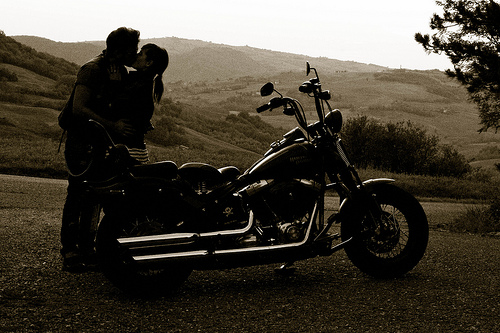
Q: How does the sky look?
A: Grey and overcast.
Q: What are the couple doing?
A: Kissing.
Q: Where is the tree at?
A: Upper right hand corner.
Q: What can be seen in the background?
A: Mountains.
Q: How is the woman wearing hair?
A: In a ponytail.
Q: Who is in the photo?
A: Two people.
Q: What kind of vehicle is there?
A: Motorcycle.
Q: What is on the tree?
A: Leaves.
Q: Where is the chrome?
A: On motorcycle.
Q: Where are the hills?
A: Behind people.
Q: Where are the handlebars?
A: On motorcycle.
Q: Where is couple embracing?
A: By motorcycle.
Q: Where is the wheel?
A: On motorcycle.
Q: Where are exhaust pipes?
A: Motorcycle.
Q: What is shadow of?
A: Mountains.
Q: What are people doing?
A: Embracing.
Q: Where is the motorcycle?
A: On the road.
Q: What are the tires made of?
A: Rubber.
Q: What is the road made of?
A: Asphalt.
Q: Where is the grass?
A: Next to the road.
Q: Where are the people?
A: Behind the motorcycle.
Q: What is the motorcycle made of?
A: Metal.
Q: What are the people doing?
A: Kissing.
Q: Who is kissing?
A: The man and the woman.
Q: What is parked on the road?
A: The motorcycle.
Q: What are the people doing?
A: Kissing.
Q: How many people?
A: Two.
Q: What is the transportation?
A: A motorcycle.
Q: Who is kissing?
A: People.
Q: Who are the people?
A: A couple.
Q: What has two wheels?
A: The motorcycle.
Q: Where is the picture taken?
A: Mountain.